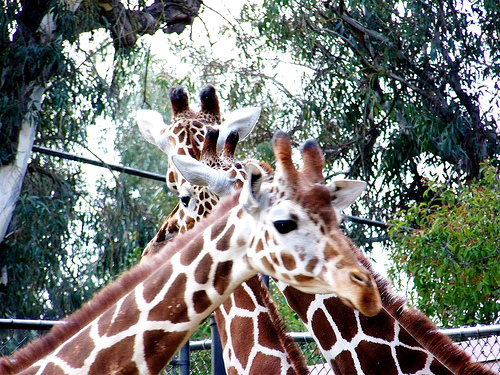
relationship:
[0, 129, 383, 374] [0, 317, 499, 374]
giraffe behind a fence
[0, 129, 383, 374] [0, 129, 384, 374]
giraffe has markings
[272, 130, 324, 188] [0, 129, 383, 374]
horns on giraffe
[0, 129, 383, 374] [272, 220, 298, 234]
giraffe has an eye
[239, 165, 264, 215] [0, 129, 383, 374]
ear on giraffe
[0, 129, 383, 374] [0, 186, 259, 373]
giraffe has a neck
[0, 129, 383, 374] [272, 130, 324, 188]
giraffe has horns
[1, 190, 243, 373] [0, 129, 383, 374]
mane on giraffe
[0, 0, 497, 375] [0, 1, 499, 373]
trees have branches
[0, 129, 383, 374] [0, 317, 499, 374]
giraffe behind fence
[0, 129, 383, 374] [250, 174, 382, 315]
giraffe has a face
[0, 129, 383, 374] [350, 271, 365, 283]
giraffe has a nostril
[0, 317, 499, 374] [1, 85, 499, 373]
fence behind giraffes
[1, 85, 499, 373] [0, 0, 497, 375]
giraffes in front of trees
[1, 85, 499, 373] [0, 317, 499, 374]
giraffes in front of fence